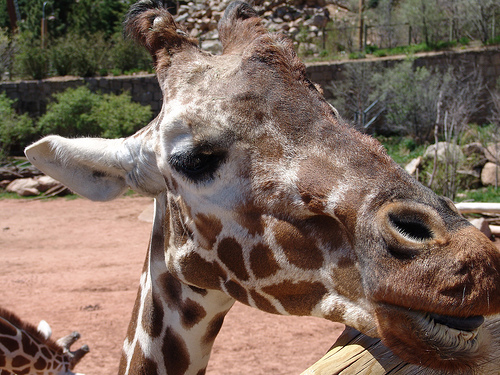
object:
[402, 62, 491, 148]
trees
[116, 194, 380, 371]
fur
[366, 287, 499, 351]
mouth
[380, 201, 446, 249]
nostril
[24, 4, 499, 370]
giraffe's head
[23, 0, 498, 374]
giraffe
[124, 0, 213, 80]
horn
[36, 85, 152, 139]
trees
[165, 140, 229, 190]
brown eye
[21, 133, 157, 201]
ear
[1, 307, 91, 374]
giraffe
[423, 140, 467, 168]
rocks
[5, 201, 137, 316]
floor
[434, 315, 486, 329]
black tongue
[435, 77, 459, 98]
leaves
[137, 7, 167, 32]
tip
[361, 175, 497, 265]
nose